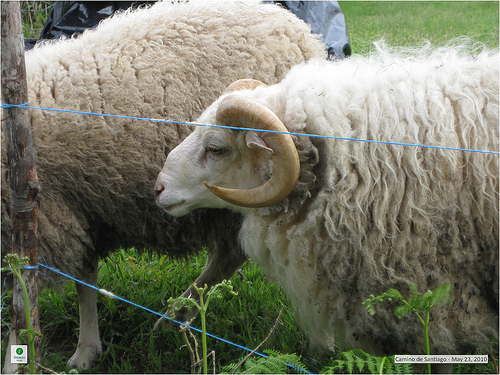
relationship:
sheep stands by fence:
[150, 32, 499, 372] [7, 6, 500, 375]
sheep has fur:
[150, 32, 499, 372] [253, 41, 500, 362]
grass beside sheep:
[82, 263, 268, 361] [150, 32, 499, 372]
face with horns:
[143, 105, 233, 221] [191, 73, 303, 220]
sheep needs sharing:
[150, 32, 499, 372] [7, 6, 500, 375]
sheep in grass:
[150, 32, 499, 372] [82, 263, 268, 361]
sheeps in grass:
[7, 6, 500, 375] [82, 263, 268, 361]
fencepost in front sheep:
[4, 2, 45, 369] [150, 32, 499, 372]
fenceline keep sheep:
[7, 6, 500, 375] [150, 32, 499, 372]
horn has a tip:
[191, 73, 303, 220] [197, 172, 245, 208]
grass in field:
[82, 263, 268, 361] [0, 290, 500, 372]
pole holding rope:
[4, 2, 45, 369] [30, 257, 305, 373]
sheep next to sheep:
[150, 32, 499, 372] [0, 2, 329, 372]